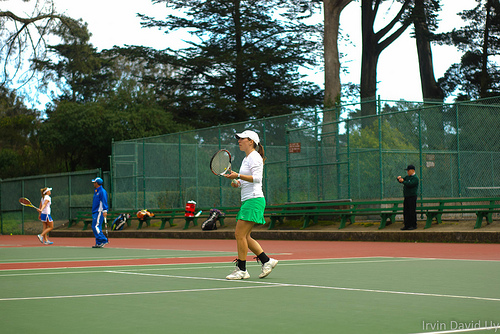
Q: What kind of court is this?
A: A tennis court.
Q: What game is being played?
A: Tennis.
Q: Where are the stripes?
A: On the court.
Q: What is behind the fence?
A: Trees.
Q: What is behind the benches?
A: Steel fence.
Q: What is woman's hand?
A: Racket.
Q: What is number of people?
A: Four.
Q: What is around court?
A: Green fence.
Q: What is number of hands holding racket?
A: Two.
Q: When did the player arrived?
A: Earlier.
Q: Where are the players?
A: At the tennis court.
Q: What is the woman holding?
A: A racket.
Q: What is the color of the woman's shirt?
A: Green.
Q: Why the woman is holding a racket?
A: To play.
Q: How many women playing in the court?
A: Two.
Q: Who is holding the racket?
A: Women.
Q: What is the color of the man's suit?
A: Blue.